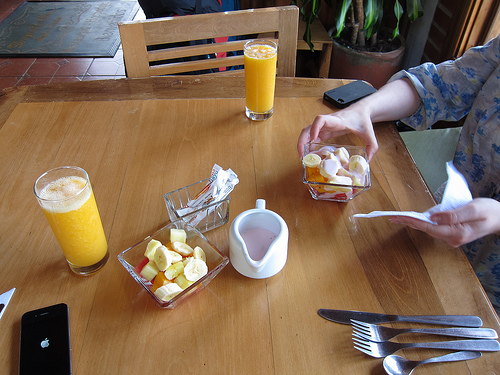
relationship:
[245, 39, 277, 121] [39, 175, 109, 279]
glass filled with orange juice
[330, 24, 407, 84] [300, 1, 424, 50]
pot under plant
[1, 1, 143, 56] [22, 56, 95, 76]
rug on top of tile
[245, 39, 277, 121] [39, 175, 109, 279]
glass with some orange juice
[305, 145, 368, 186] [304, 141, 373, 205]
fruit in square bowl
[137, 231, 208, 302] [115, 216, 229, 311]
fruit in square bowl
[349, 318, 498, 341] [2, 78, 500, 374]
fork on table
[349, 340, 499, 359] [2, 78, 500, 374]
fork on table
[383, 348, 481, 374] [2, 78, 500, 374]
spoon on table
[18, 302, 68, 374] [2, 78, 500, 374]
phone on table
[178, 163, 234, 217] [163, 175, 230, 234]
codiment inside dish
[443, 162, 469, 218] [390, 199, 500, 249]
napkin in hand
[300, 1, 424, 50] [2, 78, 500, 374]
plant behind table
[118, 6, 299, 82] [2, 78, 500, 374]
chair close to table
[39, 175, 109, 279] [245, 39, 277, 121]
orange juice in glass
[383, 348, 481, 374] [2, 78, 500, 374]
spoon on top of table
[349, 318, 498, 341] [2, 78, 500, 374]
fork on top of table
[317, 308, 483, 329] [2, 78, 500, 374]
knife on top of table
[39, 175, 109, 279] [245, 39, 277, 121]
orange juice inside of glass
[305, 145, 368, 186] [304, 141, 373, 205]
fruit in bowl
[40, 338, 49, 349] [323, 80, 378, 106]
logo on top of phone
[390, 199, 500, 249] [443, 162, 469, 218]
hand holding onto a napkin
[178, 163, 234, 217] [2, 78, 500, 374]
codiment in center of table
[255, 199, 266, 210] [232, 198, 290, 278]
handle of mug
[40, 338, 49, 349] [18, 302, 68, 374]
logo on phone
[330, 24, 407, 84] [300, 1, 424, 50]
pot of plant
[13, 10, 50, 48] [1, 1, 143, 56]
letters on black mat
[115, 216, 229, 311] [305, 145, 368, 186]
bowl filled with fruit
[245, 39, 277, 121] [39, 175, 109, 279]
glass full of orange juice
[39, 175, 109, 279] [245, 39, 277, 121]
orange juice filling up glass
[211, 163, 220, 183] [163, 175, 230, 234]
cream in dish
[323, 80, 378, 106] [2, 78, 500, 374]
phone sitting on table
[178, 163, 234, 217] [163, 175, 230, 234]
codiment in dish